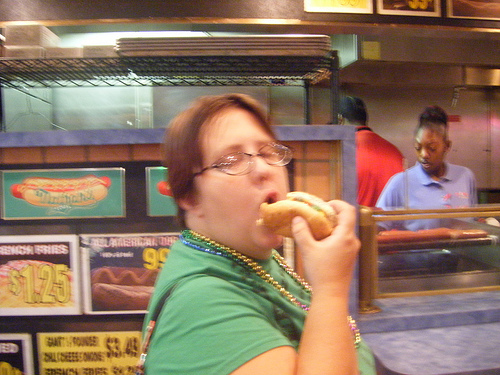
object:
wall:
[1, 140, 341, 374]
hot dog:
[10, 174, 112, 210]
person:
[127, 92, 379, 374]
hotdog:
[259, 190, 340, 243]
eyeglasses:
[188, 140, 297, 180]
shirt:
[130, 234, 379, 374]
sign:
[0, 163, 129, 222]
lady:
[370, 104, 476, 275]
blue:
[373, 159, 484, 270]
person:
[341, 94, 407, 211]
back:
[337, 86, 492, 112]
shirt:
[352, 125, 408, 210]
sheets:
[82, 45, 116, 49]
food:
[376, 224, 492, 243]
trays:
[115, 29, 332, 40]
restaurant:
[0, 1, 500, 375]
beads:
[180, 233, 362, 348]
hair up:
[410, 104, 452, 136]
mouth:
[258, 189, 288, 208]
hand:
[290, 197, 362, 297]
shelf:
[0, 53, 329, 90]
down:
[363, 245, 500, 295]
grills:
[379, 231, 497, 257]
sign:
[0, 233, 84, 319]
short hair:
[163, 91, 286, 232]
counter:
[350, 292, 499, 374]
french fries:
[0, 271, 12, 278]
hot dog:
[92, 282, 155, 310]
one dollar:
[142, 246, 161, 274]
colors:
[176, 227, 216, 254]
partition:
[355, 202, 500, 315]